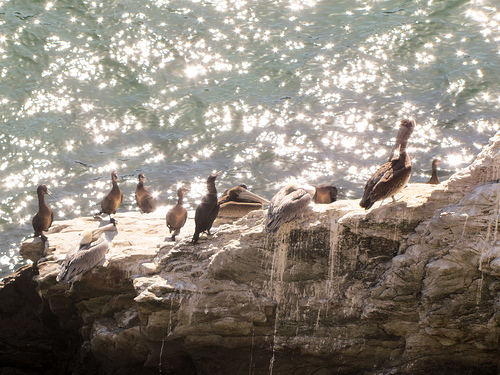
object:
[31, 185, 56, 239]
bird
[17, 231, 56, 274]
bird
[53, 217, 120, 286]
bird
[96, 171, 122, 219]
bird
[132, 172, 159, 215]
bird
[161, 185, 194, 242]
bird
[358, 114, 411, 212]
bird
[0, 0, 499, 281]
water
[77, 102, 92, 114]
sunlight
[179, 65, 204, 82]
sunlight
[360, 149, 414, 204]
body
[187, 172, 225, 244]
bird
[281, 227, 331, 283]
stain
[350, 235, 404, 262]
stain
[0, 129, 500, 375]
rock